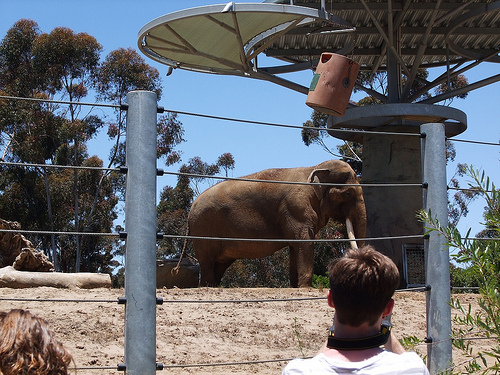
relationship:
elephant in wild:
[170, 159, 366, 288] [28, 31, 478, 369]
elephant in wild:
[170, 159, 366, 287] [50, 34, 450, 336]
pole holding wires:
[417, 117, 455, 373] [1, 92, 498, 373]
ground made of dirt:
[168, 293, 278, 364] [175, 291, 253, 363]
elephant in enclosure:
[170, 159, 366, 288] [7, 87, 494, 372]